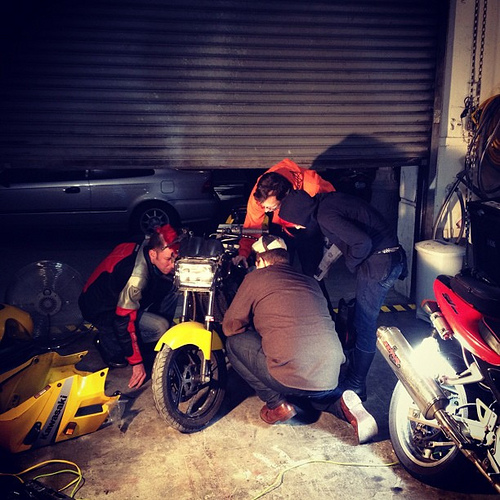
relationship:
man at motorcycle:
[232, 158, 337, 328] [145, 213, 248, 428]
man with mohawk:
[77, 222, 181, 389] [154, 221, 178, 251]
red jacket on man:
[236, 157, 337, 261] [232, 158, 337, 328]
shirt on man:
[221, 268, 343, 390] [221, 232, 379, 442]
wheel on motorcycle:
[148, 320, 233, 434] [146, 200, 273, 438]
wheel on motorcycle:
[378, 307, 499, 489] [123, 213, 288, 455]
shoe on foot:
[256, 397, 297, 429] [252, 400, 301, 426]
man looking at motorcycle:
[213, 242, 382, 449] [146, 200, 273, 438]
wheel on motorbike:
[152, 320, 228, 433] [139, 223, 285, 428]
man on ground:
[232, 158, 337, 328] [31, 344, 449, 499]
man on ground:
[276, 185, 387, 393] [31, 344, 449, 499]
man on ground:
[221, 232, 379, 442] [31, 344, 449, 499]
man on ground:
[79, 227, 179, 388] [31, 344, 449, 499]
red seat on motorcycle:
[431, 274, 495, 356] [378, 270, 497, 490]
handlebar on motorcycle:
[212, 220, 269, 237] [149, 213, 301, 435]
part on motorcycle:
[2, 347, 123, 461] [147, 230, 258, 435]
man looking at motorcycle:
[77, 222, 181, 389] [131, 232, 306, 414]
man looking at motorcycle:
[242, 147, 337, 266] [147, 220, 272, 429]